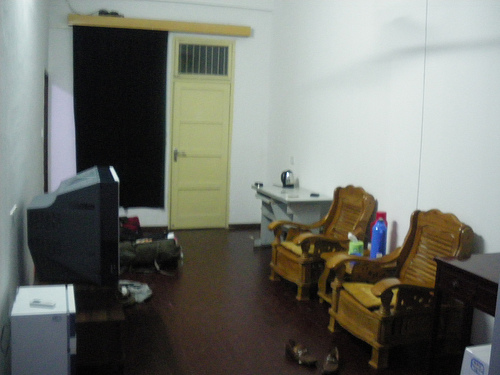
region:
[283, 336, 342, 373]
shoes in the floor by the chair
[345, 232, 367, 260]
box of tissues on the table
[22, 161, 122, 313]
tv in front of the chairs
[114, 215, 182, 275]
luggage on the floor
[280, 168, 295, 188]
silver coffee pot on white table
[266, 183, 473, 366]
matching chairs in the room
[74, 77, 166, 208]
black curtains covering window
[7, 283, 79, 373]
refrigerator by the tv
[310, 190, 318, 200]
phone on the white table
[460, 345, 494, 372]
white box under the dark brown table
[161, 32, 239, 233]
the door is yellow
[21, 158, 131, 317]
the television is black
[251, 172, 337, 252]
the desk is grey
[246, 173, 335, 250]
this is a desk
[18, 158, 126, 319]
this is a television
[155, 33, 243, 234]
this is a door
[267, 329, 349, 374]
these are shoes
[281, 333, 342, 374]
the shoes are brown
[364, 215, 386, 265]
the bottle is blue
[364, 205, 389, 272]
the bottle is between the chairs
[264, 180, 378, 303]
This is a chair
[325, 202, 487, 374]
This is a chair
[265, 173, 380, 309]
This is an arm chair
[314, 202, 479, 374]
This is an arm chair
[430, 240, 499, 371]
This is a table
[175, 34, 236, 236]
This is a door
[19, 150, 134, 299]
This is an a TV set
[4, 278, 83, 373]
This is an a speaker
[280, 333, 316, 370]
This is a shoe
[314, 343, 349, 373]
This is a shoe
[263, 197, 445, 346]
The room has two brown wooden chairs.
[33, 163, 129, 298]
A television on the stand.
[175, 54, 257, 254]
The door is yellow.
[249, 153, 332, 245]
A gray desk against the wall.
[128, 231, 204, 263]
A duffle bag is on the floor.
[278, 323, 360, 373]
Shoes on the wooden floor.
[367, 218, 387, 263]
A blue bottle sitting on the table.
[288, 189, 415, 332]
A table in between the two chairs.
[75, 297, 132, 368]
The tv stand is wooden.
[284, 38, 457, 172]
The wall is white.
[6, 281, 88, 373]
Small white piece of furniture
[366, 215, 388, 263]
Large blue bottle on table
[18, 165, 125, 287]
Large black television on table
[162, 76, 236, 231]
Light yellow door with stripes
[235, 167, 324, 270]
White desk next to the door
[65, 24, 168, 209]
Black piece of fabric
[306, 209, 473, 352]
Brown wooden chair facing television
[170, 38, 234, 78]
Vent over the yellow door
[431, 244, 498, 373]
Dark brown table next to the chair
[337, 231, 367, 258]
Bright green tissue box